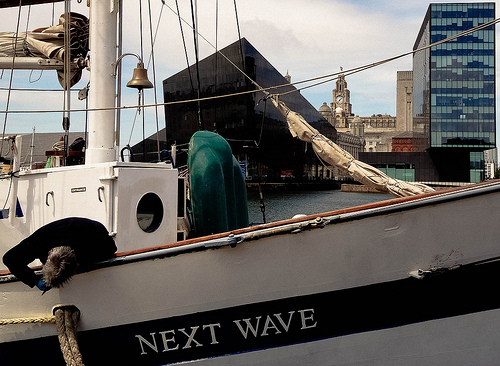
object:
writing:
[201, 323, 222, 346]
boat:
[0, 0, 500, 366]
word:
[177, 325, 204, 349]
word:
[260, 315, 281, 337]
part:
[0, 0, 499, 366]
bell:
[123, 61, 154, 91]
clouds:
[0, 85, 162, 113]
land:
[320, 62, 410, 150]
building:
[314, 65, 411, 132]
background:
[0, 0, 499, 172]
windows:
[340, 143, 343, 148]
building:
[334, 131, 365, 163]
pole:
[88, 0, 125, 167]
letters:
[134, 332, 158, 355]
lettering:
[232, 316, 262, 339]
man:
[2, 216, 118, 295]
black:
[3, 217, 117, 292]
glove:
[37, 280, 50, 292]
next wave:
[132, 305, 317, 357]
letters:
[159, 329, 180, 353]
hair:
[41, 244, 79, 289]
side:
[2, 185, 498, 366]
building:
[161, 35, 339, 182]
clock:
[335, 95, 343, 105]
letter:
[274, 310, 295, 332]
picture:
[0, 0, 497, 366]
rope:
[0, 21, 497, 117]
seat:
[183, 130, 251, 237]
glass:
[163, 37, 341, 160]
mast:
[272, 99, 435, 197]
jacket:
[2, 216, 118, 287]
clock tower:
[329, 66, 353, 128]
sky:
[9, 0, 427, 146]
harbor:
[0, 0, 428, 168]